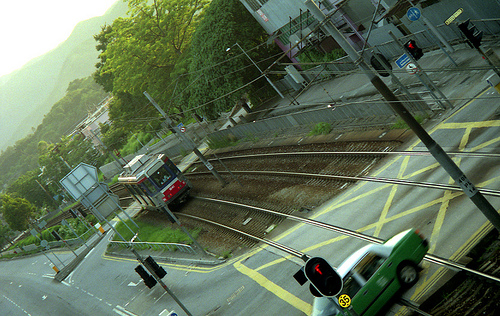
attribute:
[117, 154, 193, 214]
train car — red white, blue, gray, green, public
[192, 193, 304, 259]
train tracks — metal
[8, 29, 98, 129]
mountain range — green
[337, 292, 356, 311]
sign — yellow, 35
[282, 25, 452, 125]
lot — fenced in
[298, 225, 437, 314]
taxi cab — green, white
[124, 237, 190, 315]
sign post — metal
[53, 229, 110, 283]
island — concrete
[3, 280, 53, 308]
arrows — white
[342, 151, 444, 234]
lines — yellow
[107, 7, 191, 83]
leaves — green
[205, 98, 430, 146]
fence — metal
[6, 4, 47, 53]
sky — bright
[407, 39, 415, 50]
light — red